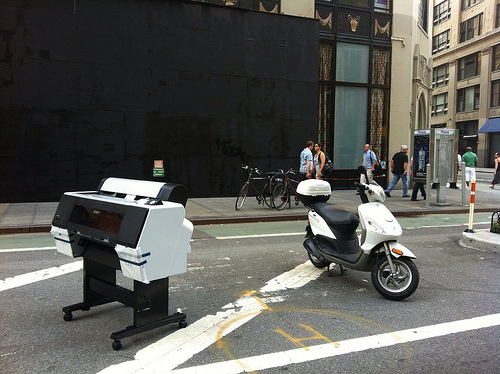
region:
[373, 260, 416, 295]
front wheel of the motorcycle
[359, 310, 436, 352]
a white line on the road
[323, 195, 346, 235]
black seat of a motocycle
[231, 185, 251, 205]
front wheel of a bicycle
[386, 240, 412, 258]
front guard of the motorcycle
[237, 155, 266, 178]
steering of a bicycle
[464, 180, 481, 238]
a red and white pole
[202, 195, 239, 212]
part of a walking path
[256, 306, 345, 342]
a H sign on the road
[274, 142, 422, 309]
a scooter on the road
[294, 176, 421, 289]
black and white scooter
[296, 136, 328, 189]
couple standing on the sidewalk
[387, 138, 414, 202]
man in a black t-shirt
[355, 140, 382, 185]
man in a blue shirt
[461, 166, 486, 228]
white pole with red stripes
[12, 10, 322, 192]
large black wall along sidewalk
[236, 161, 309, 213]
bicycles fastened to metal loop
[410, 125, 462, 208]
public pay phone on sidewalk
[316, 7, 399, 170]
tall window with paisley curtains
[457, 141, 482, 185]
man wearing green and white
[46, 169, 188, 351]
a big barbeque in the street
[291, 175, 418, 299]
a white scooter in the street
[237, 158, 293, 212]
two bikes sitting on the sidewalk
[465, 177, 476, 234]
a red and white pole in the street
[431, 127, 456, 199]
a pay phone next to the street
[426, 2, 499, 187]
a tall building on the side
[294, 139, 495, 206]
pedestrians walking on the street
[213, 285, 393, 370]
writing on the street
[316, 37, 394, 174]
a big window on the side of the building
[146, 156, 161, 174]
a sign on the building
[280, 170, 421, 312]
The motorcycle is sitting on it's kickstand.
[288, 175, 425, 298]
The motorcycle is parked in the street.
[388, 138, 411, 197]
The man is walking.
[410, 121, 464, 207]
There is a phone booth on the street corner.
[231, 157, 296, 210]
The bicycle is sitting on the sidewalk.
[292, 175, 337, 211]
The motorcycle has a trunk compartment.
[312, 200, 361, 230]
The motorcycle has a black seat.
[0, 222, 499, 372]
The asphalt is dry.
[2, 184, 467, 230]
The sidewalk is paved.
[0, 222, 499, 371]
There are painted lines on the asphalt.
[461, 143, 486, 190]
Man with green shirt and white pants.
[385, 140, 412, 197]
Man with black shirt and blue jeans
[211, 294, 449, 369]
Yellow spray painted circle and H on road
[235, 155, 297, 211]
Two bicycles locked on sidewalk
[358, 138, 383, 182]
Bald man in blue shirt.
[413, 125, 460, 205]
Pay phone booth with nobody using it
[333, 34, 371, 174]
Tall glass window on building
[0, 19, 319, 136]
Empty black wall of building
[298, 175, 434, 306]
White scooter parked in street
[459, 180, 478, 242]
Reflective marker that is white and orange